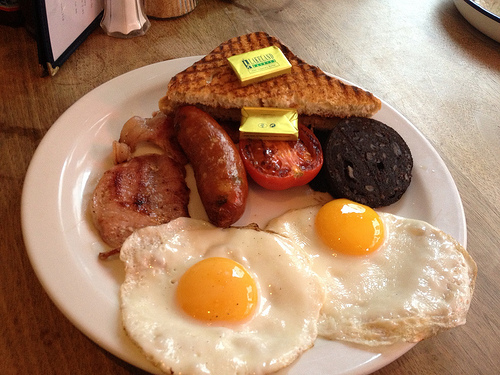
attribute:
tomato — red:
[236, 123, 317, 187]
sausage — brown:
[164, 103, 253, 223]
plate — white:
[19, 55, 473, 373]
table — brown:
[4, 3, 496, 373]